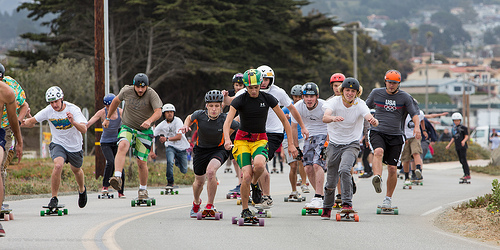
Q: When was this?
A: Daytime.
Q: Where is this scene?
A: Road.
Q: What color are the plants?
A: Green.